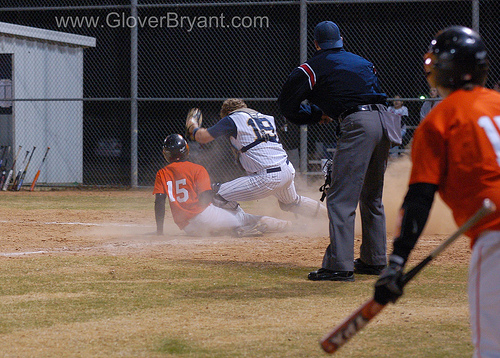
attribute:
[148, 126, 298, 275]
man — playing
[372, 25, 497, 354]
man — playing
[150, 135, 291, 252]
man — playing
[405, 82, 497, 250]
shirt — orange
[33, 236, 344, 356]
field — dusty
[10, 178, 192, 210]
grass — short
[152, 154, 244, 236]
shirt — orange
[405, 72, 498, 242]
shirt — blue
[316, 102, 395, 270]
pants — grey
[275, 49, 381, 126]
shirt — blue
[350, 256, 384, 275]
shoes — black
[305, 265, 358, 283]
shoes — black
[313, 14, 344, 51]
cap — blue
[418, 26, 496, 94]
helmet — black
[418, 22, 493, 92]
helmet — black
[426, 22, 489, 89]
helmet — blue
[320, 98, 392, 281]
pants — grey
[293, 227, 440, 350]
racket — wooden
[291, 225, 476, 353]
bat — wooden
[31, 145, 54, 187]
racket — wooden